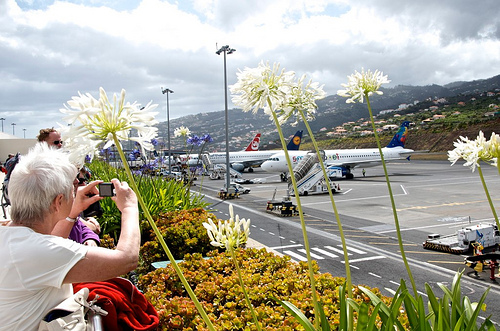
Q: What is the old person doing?
A: He's is taking a picture.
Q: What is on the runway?
A: An airplane.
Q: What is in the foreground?
A: Tall white flowers.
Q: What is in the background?
A: It's houses.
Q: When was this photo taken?
A: During the day with the sun out.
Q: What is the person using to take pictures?
A: A cell phone.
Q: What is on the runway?
A: Airplanes.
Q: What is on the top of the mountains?
A: Houses.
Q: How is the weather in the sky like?
A: Cloudy.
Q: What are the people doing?
A: Standing and watching the airplanes.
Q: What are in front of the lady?
A: Flowers.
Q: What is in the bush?
A: White flowers.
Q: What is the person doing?
A: Taking picture.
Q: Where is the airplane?
A: At the airport.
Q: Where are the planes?
A: On the tarmac.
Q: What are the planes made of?
A: Metal.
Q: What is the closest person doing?
A: Taking a picture.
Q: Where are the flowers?
A: In front of the person.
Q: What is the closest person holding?
A: A camera.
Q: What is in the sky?
A: Clouds.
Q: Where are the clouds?
A: In the sky.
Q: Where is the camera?
A: In the hands of the closest person.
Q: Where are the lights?
A: On the light poles.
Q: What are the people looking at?
A: The planes.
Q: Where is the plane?
A: On the runway.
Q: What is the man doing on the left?
A: Taking a picture.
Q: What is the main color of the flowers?
A: White.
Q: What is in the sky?
A: Clouds.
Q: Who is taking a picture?
A: The woman.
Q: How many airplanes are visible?
A: Three.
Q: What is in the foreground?
A: Flowers.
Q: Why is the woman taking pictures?
A: She likes planes.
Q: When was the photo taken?
A: Daytime.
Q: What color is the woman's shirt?
A: White.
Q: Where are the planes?
A: On the tarmac.